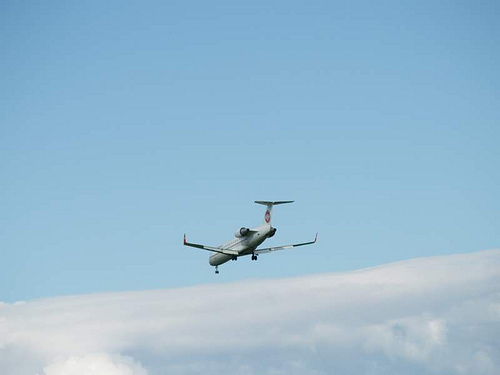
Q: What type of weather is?
A: It is clear.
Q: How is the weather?
A: It is clear.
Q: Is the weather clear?
A: Yes, it is clear.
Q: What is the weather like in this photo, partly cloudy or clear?
A: It is clear.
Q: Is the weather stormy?
A: No, it is clear.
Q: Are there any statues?
A: No, there are no statues.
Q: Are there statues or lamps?
A: No, there are no statues or lamps.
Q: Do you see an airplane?
A: Yes, there is an airplane.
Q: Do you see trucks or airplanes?
A: Yes, there is an airplane.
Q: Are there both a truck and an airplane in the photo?
A: No, there is an airplane but no trucks.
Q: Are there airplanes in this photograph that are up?
A: Yes, there is an airplane that is up.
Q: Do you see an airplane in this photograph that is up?
A: Yes, there is an airplane that is up.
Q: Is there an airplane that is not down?
A: Yes, there is an airplane that is up.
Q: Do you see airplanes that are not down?
A: Yes, there is an airplane that is up .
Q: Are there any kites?
A: No, there are no kites.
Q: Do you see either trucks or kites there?
A: No, there are no kites or trucks.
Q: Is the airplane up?
A: Yes, the airplane is up.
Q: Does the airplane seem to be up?
A: Yes, the airplane is up.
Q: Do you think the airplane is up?
A: Yes, the airplane is up.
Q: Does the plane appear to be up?
A: Yes, the plane is up.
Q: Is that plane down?
A: No, the plane is up.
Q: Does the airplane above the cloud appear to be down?
A: No, the plane is up.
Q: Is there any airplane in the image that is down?
A: No, there is an airplane but it is up.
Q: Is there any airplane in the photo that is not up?
A: No, there is an airplane but it is up.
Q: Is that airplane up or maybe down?
A: The airplane is up.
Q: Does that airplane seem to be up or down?
A: The airplane is up.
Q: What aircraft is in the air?
A: The aircraft is an airplane.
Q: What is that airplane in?
A: The airplane is in the air.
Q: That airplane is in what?
A: The airplane is in the air.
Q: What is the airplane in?
A: The airplane is in the air.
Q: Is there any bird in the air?
A: No, there is an airplane in the air.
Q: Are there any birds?
A: No, there are no birds.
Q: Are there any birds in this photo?
A: No, there are no birds.